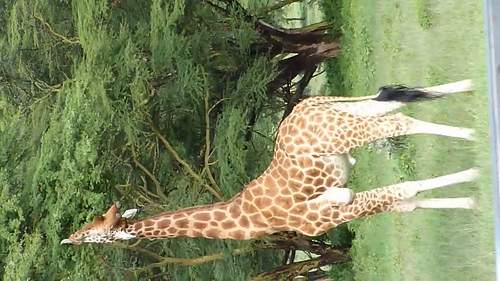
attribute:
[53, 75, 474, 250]
giraffe — here, brown, white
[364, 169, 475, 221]
front legs — white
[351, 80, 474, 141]
back legs — white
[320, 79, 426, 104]
tail — brown, black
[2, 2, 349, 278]
tree — lush, green, leafy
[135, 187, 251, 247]
neck — long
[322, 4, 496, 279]
field — grassy, green, tall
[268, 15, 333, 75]
trunk — large, brown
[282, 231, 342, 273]
trunk — large, brown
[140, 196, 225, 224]
mane — brown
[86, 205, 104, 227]
ossicles — brown